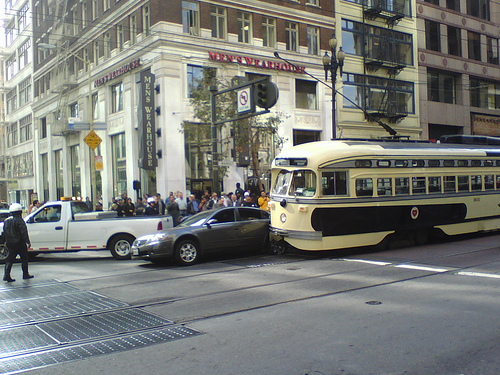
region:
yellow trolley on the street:
[276, 127, 498, 270]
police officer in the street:
[4, 192, 46, 283]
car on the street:
[146, 202, 276, 269]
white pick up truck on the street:
[30, 187, 164, 264]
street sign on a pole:
[81, 120, 111, 181]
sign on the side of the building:
[130, 66, 175, 173]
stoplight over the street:
[219, 78, 311, 133]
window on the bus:
[321, 162, 358, 208]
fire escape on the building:
[361, 81, 428, 128]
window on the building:
[303, 23, 326, 60]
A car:
[145, 213, 228, 264]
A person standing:
[0, 201, 47, 277]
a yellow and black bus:
[264, 150, 486, 236]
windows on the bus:
[346, 180, 467, 195]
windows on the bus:
[214, 212, 249, 219]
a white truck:
[34, 198, 117, 256]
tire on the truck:
[108, 242, 128, 254]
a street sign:
[231, 88, 262, 115]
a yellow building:
[340, 71, 429, 141]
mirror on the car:
[205, 218, 220, 228]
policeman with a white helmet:
[0, 198, 36, 285]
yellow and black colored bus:
[263, 127, 498, 253]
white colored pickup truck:
[4, 193, 177, 260]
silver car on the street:
[130, 197, 289, 267]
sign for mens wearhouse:
[136, 70, 163, 180]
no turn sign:
[233, 87, 253, 118]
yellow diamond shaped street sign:
[82, 126, 105, 153]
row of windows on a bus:
[353, 170, 498, 203]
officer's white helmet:
[6, 197, 22, 216]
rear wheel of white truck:
[105, 231, 139, 264]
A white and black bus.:
[272, 132, 497, 250]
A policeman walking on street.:
[2, 204, 42, 280]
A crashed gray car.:
[125, 206, 302, 264]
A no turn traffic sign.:
[236, 82, 250, 114]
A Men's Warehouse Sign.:
[132, 70, 162, 170]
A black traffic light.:
[250, 82, 275, 108]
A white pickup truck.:
[2, 200, 171, 253]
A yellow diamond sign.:
[82, 131, 105, 146]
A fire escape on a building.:
[361, 2, 418, 126]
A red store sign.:
[200, 46, 317, 76]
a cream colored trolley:
[263, 129, 494, 264]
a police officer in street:
[1, 196, 31, 281]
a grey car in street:
[129, 197, 277, 265]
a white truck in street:
[8, 195, 179, 259]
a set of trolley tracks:
[3, 221, 296, 311]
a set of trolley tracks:
[1, 234, 498, 368]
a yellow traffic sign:
[78, 129, 102, 152]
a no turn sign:
[232, 97, 252, 116]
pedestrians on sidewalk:
[127, 188, 266, 212]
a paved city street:
[6, 230, 498, 373]